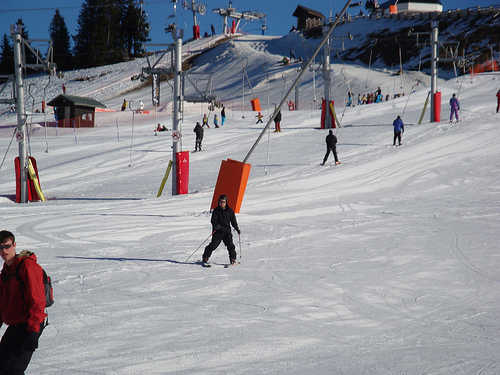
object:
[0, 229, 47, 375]
boy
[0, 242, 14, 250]
glasses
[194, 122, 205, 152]
people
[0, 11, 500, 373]
ski resort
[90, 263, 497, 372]
snow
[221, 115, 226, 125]
pants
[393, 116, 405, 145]
person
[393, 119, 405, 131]
jacket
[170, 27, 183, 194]
post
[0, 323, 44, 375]
pants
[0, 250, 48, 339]
jacket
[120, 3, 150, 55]
tree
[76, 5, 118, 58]
tree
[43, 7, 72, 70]
tree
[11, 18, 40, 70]
tree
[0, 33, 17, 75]
tree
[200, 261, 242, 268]
skis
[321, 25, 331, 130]
pole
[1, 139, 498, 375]
floor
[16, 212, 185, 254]
tracks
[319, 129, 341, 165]
skii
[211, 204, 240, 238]
black coat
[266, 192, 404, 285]
snow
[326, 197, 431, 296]
snow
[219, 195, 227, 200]
cap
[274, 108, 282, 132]
people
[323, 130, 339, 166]
people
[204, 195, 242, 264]
people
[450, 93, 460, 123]
people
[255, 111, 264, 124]
people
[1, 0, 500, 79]
sky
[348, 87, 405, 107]
people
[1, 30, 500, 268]
slopes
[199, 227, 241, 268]
sink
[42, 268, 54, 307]
backpack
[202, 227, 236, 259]
pants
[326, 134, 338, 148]
jacket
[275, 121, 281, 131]
pants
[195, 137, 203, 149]
pants